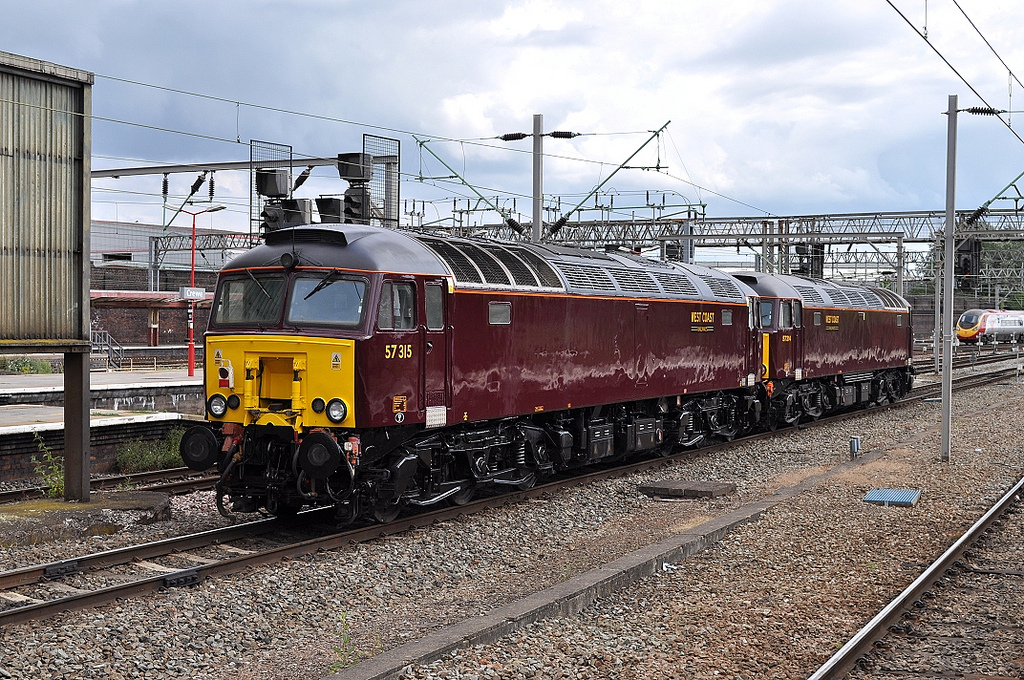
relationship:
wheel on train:
[548, 429, 605, 462] [204, 223, 937, 492]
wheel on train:
[768, 397, 795, 414] [204, 223, 937, 492]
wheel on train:
[807, 386, 839, 418] [204, 223, 937, 492]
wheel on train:
[873, 381, 903, 410] [213, 197, 935, 498]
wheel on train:
[895, 370, 914, 389] [204, 223, 937, 492]